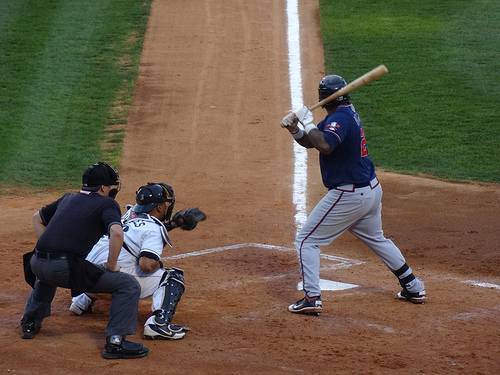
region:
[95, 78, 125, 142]
bald spot on baseball field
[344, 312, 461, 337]
blurry white chalk lines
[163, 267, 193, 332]
long black knee pad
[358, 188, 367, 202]
black button on back of pants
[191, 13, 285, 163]
tracks on the red clay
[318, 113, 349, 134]
logo on shirt's arm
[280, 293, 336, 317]
blue and white baseball shoes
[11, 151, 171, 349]
umpire hunched over player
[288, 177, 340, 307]
stripes down the side of pants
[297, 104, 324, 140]
white gloves on player's hand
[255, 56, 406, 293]
a man holding a bat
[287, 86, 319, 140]
a man wearing white gloves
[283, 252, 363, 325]
home plate on a baseball field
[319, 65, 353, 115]
a man wearing a blue helmet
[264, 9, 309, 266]
white chalk line on a baseball field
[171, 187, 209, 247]
a man wearing a baseball glove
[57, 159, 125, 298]
a man bent down with his hand on his knee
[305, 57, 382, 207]
a man wearing a blue shirt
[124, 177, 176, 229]
a man wearing a catchers mask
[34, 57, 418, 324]
three men playing baseball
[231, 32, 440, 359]
batter in the batter's box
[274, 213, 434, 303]
legs of the player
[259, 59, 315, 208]
white third base line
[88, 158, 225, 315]
catcher behind the plate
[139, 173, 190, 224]
mask of the catcher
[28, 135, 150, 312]
umpire behind the catcher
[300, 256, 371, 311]
plate under the batter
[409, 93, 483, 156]
green grass in the infield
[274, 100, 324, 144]
gloves on the batter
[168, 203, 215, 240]
glove of the catcher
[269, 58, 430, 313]
A batter standing at home plate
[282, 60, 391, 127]
The baseball bat in the batter's hands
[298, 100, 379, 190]
The batter's dark blue jersey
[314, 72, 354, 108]
A shiny black batter's helmet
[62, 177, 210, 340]
A catcher crouched behind home plate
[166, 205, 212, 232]
The catcher's dark leather mitt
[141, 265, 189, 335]
A black shin guard on the catcher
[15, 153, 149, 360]
An umpire crouching behind the catcher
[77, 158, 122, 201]
The umpire's dark face guard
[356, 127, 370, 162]
A red number on the batter's jersey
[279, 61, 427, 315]
Batter Getting Ready To Bat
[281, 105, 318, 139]
White Baseball Gloves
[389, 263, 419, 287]
Two Black Straps On Players Right Leg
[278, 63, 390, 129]
Baseball bat positioned to hit the ball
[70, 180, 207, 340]
Catcher ready to catch the ball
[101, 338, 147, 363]
Umpire's Shiny Black Shoes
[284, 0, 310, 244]
White Line Down The Dirt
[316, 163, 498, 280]
Dark Brown Dirt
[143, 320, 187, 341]
Black And White Nike Clets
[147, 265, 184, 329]
Black Shin Protectors on the catcher's leg